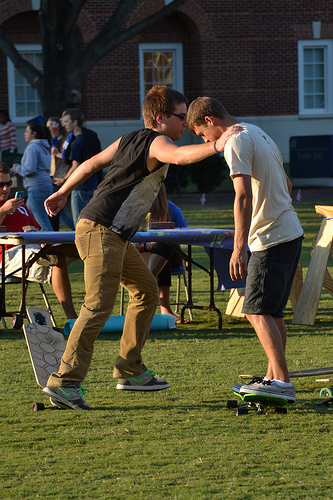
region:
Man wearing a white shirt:
[185, 98, 306, 405]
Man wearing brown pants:
[46, 92, 242, 408]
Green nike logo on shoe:
[120, 374, 149, 388]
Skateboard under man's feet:
[222, 376, 298, 422]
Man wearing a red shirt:
[0, 162, 95, 340]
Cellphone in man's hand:
[9, 188, 25, 211]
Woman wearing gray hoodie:
[12, 124, 52, 238]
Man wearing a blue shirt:
[57, 111, 101, 230]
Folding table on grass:
[0, 222, 240, 356]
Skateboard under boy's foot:
[16, 301, 100, 418]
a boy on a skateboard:
[206, 87, 308, 426]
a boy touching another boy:
[54, 64, 306, 268]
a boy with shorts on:
[238, 179, 324, 361]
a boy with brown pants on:
[35, 188, 185, 413]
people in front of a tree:
[23, 86, 127, 205]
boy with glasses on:
[145, 77, 211, 189]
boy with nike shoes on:
[43, 349, 194, 421]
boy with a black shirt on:
[70, 121, 206, 245]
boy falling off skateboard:
[14, 47, 190, 431]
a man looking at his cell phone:
[0, 145, 63, 270]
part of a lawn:
[296, 445, 305, 467]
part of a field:
[149, 460, 159, 473]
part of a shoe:
[267, 386, 277, 396]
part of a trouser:
[119, 369, 122, 372]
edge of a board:
[42, 354, 55, 365]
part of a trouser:
[145, 322, 149, 327]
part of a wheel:
[240, 410, 252, 415]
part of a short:
[262, 301, 265, 306]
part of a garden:
[175, 439, 184, 452]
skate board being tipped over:
[22, 305, 68, 413]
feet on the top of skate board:
[228, 363, 296, 422]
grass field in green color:
[5, 410, 330, 495]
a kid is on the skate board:
[187, 94, 305, 424]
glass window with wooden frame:
[290, 18, 331, 211]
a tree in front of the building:
[4, 5, 161, 116]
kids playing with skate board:
[26, 84, 299, 421]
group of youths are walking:
[4, 111, 105, 255]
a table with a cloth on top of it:
[0, 225, 241, 351]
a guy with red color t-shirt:
[1, 172, 79, 334]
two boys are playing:
[40, 24, 305, 412]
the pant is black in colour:
[66, 228, 150, 349]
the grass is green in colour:
[55, 408, 217, 499]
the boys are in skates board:
[39, 79, 295, 420]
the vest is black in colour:
[83, 132, 167, 225]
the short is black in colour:
[238, 234, 302, 326]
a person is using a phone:
[3, 159, 65, 281]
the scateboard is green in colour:
[209, 378, 313, 430]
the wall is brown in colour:
[199, 3, 259, 91]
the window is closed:
[296, 46, 331, 116]